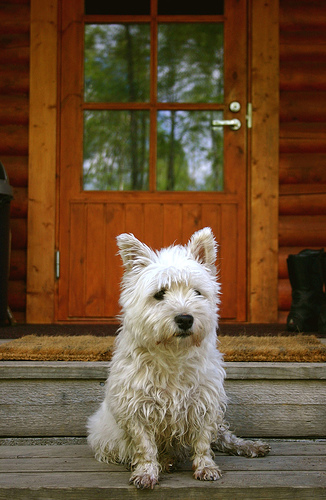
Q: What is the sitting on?
A: A step.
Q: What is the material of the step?
A: Wood.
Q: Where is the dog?
A: Front of the house.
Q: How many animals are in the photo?
A: One.